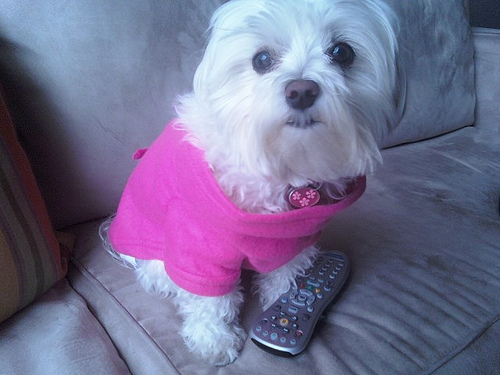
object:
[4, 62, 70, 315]
pillow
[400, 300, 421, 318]
wrinkles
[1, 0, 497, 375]
couch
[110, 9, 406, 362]
dog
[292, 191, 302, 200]
flower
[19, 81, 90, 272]
shadow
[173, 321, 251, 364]
paw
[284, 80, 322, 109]
black nose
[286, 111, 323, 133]
mouth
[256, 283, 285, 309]
paw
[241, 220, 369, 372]
remote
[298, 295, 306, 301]
buttons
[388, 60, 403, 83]
ear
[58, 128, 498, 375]
cushion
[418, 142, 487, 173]
stains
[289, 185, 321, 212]
collar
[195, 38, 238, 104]
ear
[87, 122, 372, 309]
dog clothing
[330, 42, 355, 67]
eye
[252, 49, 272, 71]
eye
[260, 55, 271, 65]
light